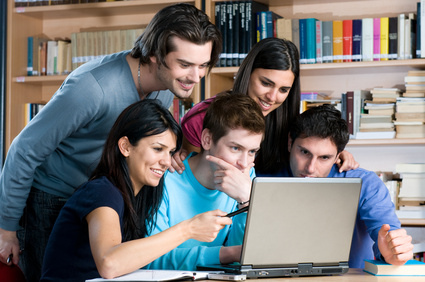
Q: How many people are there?
A: Five.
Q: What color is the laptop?
A: Silver.